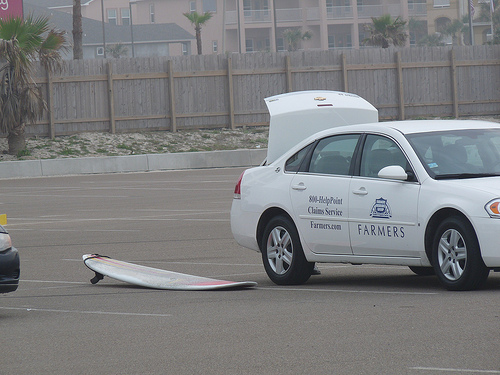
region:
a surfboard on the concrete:
[80, 251, 257, 296]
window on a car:
[305, 133, 352, 174]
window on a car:
[360, 131, 412, 178]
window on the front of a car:
[408, 123, 499, 175]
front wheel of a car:
[426, 214, 486, 286]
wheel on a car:
[259, 213, 314, 288]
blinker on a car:
[491, 199, 498, 214]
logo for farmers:
[353, 198, 405, 238]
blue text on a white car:
[303, 193, 343, 233]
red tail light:
[232, 173, 242, 197]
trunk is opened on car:
[274, 100, 386, 141]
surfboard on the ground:
[54, 246, 260, 293]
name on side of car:
[286, 197, 420, 264]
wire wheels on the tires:
[439, 233, 467, 283]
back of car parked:
[1, 202, 30, 309]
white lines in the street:
[51, 154, 228, 231]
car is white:
[236, 119, 498, 294]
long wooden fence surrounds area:
[31, 49, 494, 101]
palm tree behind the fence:
[359, 13, 420, 53]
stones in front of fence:
[56, 135, 270, 146]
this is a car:
[262, 32, 499, 299]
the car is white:
[263, 122, 454, 373]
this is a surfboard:
[68, 162, 218, 294]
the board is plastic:
[47, 174, 215, 373]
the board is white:
[96, 244, 252, 332]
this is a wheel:
[195, 149, 330, 372]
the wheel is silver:
[210, 232, 410, 288]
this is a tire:
[381, 249, 496, 294]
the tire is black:
[436, 229, 487, 286]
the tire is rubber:
[276, 202, 343, 320]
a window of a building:
[243, 39, 253, 50]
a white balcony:
[273, 5, 306, 27]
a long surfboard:
[75, 248, 260, 290]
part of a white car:
[225, 87, 498, 288]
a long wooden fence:
[27, 43, 499, 133]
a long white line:
[2, 300, 175, 318]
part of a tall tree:
[179, 10, 216, 52]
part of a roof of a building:
[80, 20, 193, 42]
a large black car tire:
[256, 215, 303, 281]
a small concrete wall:
[3, 145, 268, 179]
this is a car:
[199, 96, 369, 359]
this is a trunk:
[200, 81, 263, 187]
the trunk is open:
[262, 53, 347, 148]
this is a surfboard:
[81, 231, 205, 345]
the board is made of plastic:
[51, 243, 211, 313]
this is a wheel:
[230, 232, 305, 295]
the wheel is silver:
[261, 200, 308, 333]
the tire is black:
[401, 250, 470, 260]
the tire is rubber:
[460, 257, 469, 277]